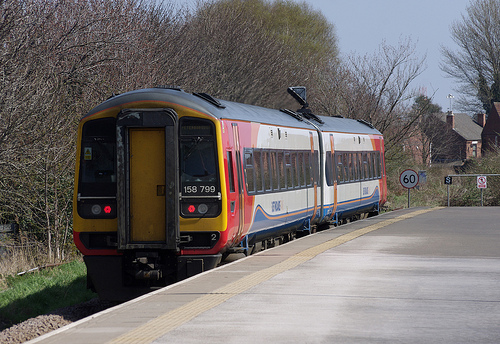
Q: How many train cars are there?
A: Two.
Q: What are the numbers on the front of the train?
A: 158 799.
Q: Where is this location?
A: Train station.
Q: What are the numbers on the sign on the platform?
A: 60.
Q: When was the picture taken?
A: Daytime.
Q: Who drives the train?
A: Conductor.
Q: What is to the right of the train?
A: Platform.